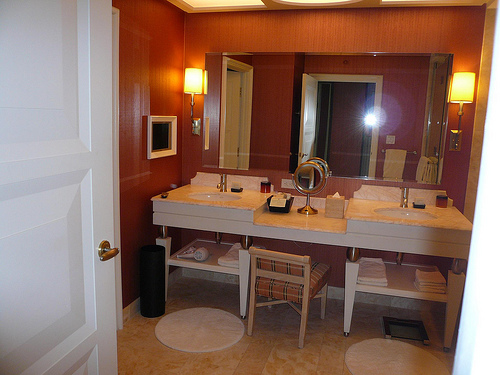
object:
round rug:
[342, 337, 451, 374]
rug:
[152, 306, 248, 354]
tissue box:
[322, 194, 347, 220]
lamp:
[445, 72, 476, 153]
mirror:
[200, 47, 453, 189]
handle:
[95, 238, 118, 262]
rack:
[380, 146, 416, 158]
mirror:
[289, 161, 329, 198]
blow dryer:
[173, 246, 208, 263]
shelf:
[168, 238, 242, 277]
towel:
[356, 256, 386, 287]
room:
[0, 0, 499, 374]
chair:
[244, 246, 332, 349]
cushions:
[254, 256, 304, 277]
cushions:
[252, 258, 332, 304]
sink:
[370, 206, 436, 223]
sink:
[187, 190, 242, 204]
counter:
[150, 172, 471, 262]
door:
[0, 0, 120, 374]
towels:
[413, 268, 448, 293]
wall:
[180, 6, 485, 311]